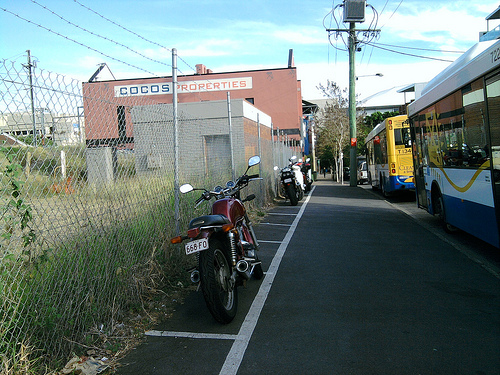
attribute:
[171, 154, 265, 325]
motorcycle — red, parked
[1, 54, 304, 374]
fence — metal, chain link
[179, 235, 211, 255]
license plate — white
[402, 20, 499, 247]
bus — white, blue, parked, yellow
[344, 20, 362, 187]
pole — green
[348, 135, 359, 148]
sign — red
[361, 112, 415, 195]
bus — yellow, blue, parked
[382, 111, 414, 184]
back — yellow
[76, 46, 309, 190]
building — cocos properties, two-story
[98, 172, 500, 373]
sidewalk — dark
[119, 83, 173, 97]
letters — blue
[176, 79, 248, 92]
letters — orange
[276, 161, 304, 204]
motorcycle — white, black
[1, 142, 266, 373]
grass — green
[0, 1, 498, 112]
sky — blue